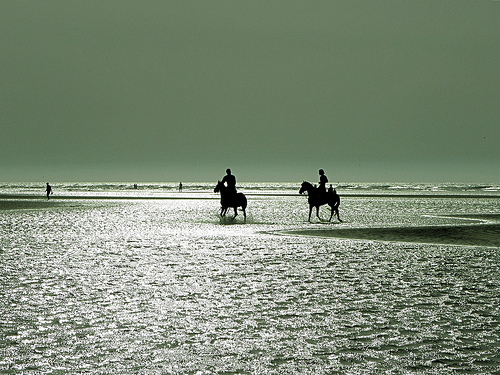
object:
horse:
[214, 180, 248, 223]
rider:
[221, 168, 237, 193]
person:
[44, 182, 53, 200]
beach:
[0, 194, 499, 373]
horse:
[299, 180, 344, 223]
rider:
[317, 169, 328, 193]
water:
[32, 203, 61, 221]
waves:
[371, 184, 391, 189]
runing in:
[209, 230, 245, 243]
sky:
[124, 47, 167, 78]